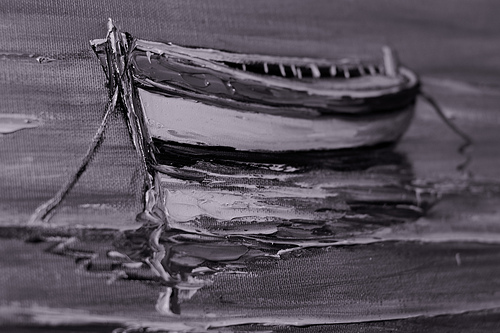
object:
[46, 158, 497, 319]
water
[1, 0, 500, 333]
boat painting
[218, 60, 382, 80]
cabin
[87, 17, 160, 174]
part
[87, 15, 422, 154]
boat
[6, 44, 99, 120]
grey paint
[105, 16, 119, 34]
tip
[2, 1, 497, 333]
sea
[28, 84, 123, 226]
rope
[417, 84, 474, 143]
rope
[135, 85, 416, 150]
stripe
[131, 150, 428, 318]
boat shadow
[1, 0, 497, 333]
canvas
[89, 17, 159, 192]
post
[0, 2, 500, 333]
painting